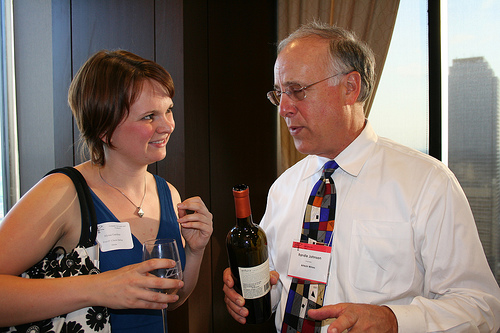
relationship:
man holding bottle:
[222, 21, 490, 332] [222, 181, 274, 332]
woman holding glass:
[3, 40, 215, 332] [144, 235, 185, 331]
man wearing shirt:
[222, 21, 490, 332] [246, 128, 488, 332]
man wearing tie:
[222, 21, 490, 332] [286, 165, 346, 332]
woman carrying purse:
[3, 40, 215, 332] [11, 161, 111, 332]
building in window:
[441, 52, 499, 283] [274, 6, 499, 294]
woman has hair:
[3, 40, 215, 332] [66, 53, 176, 164]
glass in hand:
[144, 235, 185, 331] [120, 257, 185, 316]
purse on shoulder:
[11, 161, 111, 332] [39, 170, 105, 245]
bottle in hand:
[222, 181, 274, 332] [221, 269, 275, 323]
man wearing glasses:
[222, 21, 490, 332] [264, 64, 354, 105]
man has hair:
[222, 21, 490, 332] [273, 25, 383, 99]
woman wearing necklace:
[3, 40, 215, 332] [99, 170, 157, 222]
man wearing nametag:
[222, 21, 490, 332] [286, 238, 341, 286]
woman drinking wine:
[3, 40, 215, 332] [225, 184, 279, 332]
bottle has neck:
[222, 181, 274, 332] [232, 184, 253, 219]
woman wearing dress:
[3, 40, 215, 332] [82, 170, 184, 332]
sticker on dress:
[92, 219, 134, 251] [82, 170, 184, 332]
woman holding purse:
[3, 40, 215, 332] [11, 161, 111, 332]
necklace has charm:
[99, 170, 157, 222] [133, 203, 148, 219]